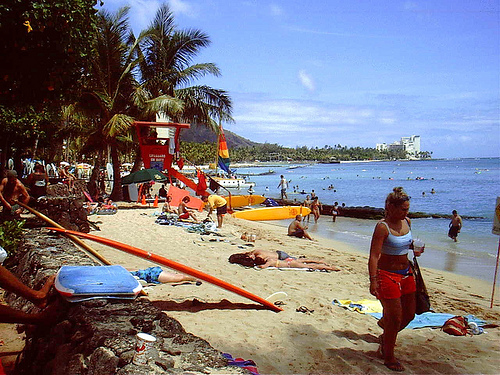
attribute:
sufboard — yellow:
[227, 201, 313, 221]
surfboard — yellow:
[231, 201, 317, 222]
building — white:
[404, 132, 430, 156]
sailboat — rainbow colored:
[148, 146, 191, 163]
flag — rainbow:
[212, 123, 238, 185]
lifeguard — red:
[96, 75, 230, 196]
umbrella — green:
[119, 168, 168, 186]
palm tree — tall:
[124, 4, 236, 211]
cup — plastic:
[408, 234, 438, 262]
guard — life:
[147, 116, 167, 153]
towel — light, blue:
[338, 284, 498, 352]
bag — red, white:
[441, 307, 482, 341]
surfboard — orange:
[110, 239, 180, 272]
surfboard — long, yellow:
[226, 203, 318, 223]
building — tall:
[372, 131, 427, 163]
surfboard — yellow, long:
[223, 194, 266, 209]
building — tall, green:
[375, 134, 422, 159]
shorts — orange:
[378, 270, 417, 298]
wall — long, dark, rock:
[14, 220, 239, 372]